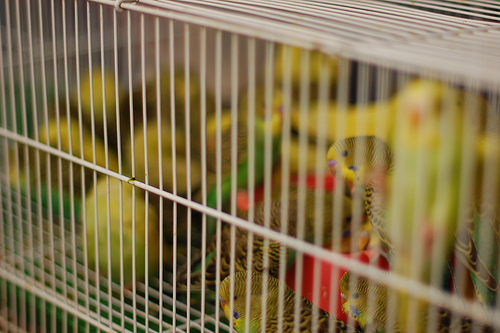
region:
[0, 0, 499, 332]
A Cage full of birds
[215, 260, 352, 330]
A parakeet in the cage.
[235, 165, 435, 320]
A feeding dish in the cage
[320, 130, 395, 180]
A head of a parakeet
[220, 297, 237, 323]
A beak on a parakeet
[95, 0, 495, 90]
The top of a bird cage.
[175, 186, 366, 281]
A parakeet eating in the cage.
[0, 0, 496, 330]
the side of a bird cage.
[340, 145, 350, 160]
An eye on a parakeet.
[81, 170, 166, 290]
A parakeet sitting in the cage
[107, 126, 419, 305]
the birds are in the cage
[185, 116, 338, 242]
the bird is green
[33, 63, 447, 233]
the cage is made of metal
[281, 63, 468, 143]
a yellow bird is in the cage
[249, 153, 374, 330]
the feeder is red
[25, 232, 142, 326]
the cage has two levels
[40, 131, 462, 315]
a mixed variety of birds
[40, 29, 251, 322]
a group of yellow birds are in the cage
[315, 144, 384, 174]
the bird has a yellow beak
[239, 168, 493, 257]
the bird is eating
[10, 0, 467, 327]
a white cage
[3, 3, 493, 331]
the cage is white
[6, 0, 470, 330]
a metal cage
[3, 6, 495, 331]
a white, metal cage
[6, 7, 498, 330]
a white bird cage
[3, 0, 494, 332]
a metal bird cage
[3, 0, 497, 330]
there are a lot of birds in the cage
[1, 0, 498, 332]
the birds in the cage are yellow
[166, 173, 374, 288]
this bird is drinking water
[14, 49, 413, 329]
the birds are yellow, black, and green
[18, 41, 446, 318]
parakeets in a cage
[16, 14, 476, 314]
the parakeets are green and yellow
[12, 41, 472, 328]
many birds in a cage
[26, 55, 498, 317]
the cage is white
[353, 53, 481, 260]
this bird clings to the cage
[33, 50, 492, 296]
the birds are crowded in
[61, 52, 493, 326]
this is a flock of birds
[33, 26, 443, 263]
the species is parakeets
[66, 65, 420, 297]
the birds are captive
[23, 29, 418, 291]
the birds are pets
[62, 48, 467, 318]
birds in a cage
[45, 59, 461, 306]
these birds are yellow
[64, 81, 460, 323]
some of these birds have red and green feathers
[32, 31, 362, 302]
this is steel cage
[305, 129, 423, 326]
the birds are being contained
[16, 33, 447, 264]
these birds have been captured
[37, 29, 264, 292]
the birds are for research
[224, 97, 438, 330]
the chics are seperated from their parents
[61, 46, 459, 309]
thse birds are at a pet store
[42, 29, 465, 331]
this picture is very blurry